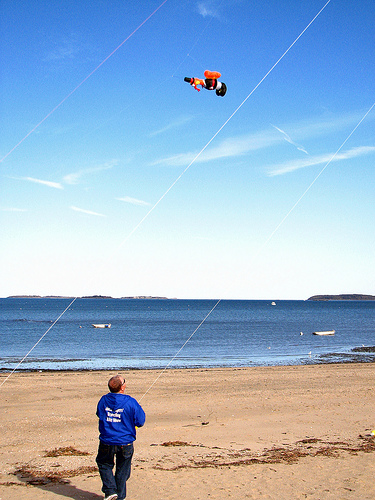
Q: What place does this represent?
A: It represents the beach.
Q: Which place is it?
A: It is a beach.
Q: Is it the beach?
A: Yes, it is the beach.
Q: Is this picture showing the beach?
A: Yes, it is showing the beach.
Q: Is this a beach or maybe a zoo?
A: It is a beach.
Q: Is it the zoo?
A: No, it is the beach.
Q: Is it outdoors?
A: Yes, it is outdoors.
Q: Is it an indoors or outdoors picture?
A: It is outdoors.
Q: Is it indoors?
A: No, it is outdoors.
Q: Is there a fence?
A: No, there are no fences.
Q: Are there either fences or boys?
A: No, there are no fences or boys.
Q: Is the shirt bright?
A: Yes, the shirt is bright.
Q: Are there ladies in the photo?
A: No, there are no ladies.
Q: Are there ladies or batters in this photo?
A: No, there are no ladies or batters.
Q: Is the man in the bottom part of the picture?
A: Yes, the man is in the bottom of the image.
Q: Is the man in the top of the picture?
A: No, the man is in the bottom of the image.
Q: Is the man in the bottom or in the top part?
A: The man is in the bottom of the image.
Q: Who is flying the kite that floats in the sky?
A: The man is flying the kite.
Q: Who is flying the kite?
A: The man is flying the kite.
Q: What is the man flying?
A: The man is flying the kite.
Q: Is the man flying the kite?
A: Yes, the man is flying the kite.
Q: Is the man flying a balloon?
A: No, the man is flying the kite.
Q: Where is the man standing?
A: The man is standing at the beach.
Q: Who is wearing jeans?
A: The man is wearing jeans.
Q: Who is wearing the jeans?
A: The man is wearing jeans.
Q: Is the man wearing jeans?
A: Yes, the man is wearing jeans.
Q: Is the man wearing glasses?
A: No, the man is wearing jeans.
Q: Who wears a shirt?
A: The man wears a shirt.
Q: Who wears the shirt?
A: The man wears a shirt.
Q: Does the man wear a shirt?
A: Yes, the man wears a shirt.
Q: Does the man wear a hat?
A: No, the man wears a shirt.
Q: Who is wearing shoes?
A: The man is wearing shoes.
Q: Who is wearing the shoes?
A: The man is wearing shoes.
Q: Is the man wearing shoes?
A: Yes, the man is wearing shoes.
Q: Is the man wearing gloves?
A: No, the man is wearing shoes.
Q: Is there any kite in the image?
A: Yes, there is a kite.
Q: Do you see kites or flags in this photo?
A: Yes, there is a kite.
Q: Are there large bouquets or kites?
A: Yes, there is a large kite.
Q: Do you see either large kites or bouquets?
A: Yes, there is a large kite.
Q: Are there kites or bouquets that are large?
A: Yes, the kite is large.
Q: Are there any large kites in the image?
A: Yes, there is a large kite.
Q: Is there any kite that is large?
A: Yes, there is a kite that is large.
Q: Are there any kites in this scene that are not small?
A: Yes, there is a large kite.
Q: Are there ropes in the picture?
A: No, there are no ropes.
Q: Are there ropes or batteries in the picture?
A: No, there are no ropes or batteries.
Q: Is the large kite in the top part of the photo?
A: Yes, the kite is in the top of the image.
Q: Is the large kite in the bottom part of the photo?
A: No, the kite is in the top of the image.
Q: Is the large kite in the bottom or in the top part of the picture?
A: The kite is in the top of the image.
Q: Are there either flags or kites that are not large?
A: No, there is a kite but it is large.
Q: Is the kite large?
A: Yes, the kite is large.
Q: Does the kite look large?
A: Yes, the kite is large.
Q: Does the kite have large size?
A: Yes, the kite is large.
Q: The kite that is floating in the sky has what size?
A: The kite is large.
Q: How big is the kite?
A: The kite is large.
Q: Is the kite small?
A: No, the kite is large.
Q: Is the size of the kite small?
A: No, the kite is large.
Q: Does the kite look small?
A: No, the kite is large.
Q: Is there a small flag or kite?
A: No, there is a kite but it is large.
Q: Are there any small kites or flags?
A: No, there is a kite but it is large.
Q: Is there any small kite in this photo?
A: No, there is a kite but it is large.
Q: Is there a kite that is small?
A: No, there is a kite but it is large.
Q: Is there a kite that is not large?
A: No, there is a kite but it is large.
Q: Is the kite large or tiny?
A: The kite is large.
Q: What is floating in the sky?
A: The kite is floating in the sky.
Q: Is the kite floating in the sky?
A: Yes, the kite is floating in the sky.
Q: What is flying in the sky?
A: The kite is flying in the sky.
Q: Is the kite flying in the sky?
A: Yes, the kite is flying in the sky.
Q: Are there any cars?
A: No, there are no cars.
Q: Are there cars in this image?
A: No, there are no cars.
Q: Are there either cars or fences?
A: No, there are no cars or fences.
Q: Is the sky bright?
A: Yes, the sky is bright.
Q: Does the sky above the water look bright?
A: Yes, the sky is bright.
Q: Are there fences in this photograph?
A: No, there are no fences.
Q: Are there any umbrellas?
A: No, there are no umbrellas.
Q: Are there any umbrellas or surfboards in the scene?
A: No, there are no umbrellas or surfboards.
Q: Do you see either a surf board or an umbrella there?
A: No, there are no umbrellas or surfboards.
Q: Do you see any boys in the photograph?
A: No, there are no boys.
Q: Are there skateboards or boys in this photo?
A: No, there are no boys or skateboards.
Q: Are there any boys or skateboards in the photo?
A: No, there are no boys or skateboards.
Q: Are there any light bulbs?
A: No, there are no light bulbs.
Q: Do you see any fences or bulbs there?
A: No, there are no bulbs or fences.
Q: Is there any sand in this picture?
A: Yes, there is sand.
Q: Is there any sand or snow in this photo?
A: Yes, there is sand.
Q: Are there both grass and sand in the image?
A: No, there is sand but no grass.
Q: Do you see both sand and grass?
A: No, there is sand but no grass.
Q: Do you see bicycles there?
A: No, there are no bicycles.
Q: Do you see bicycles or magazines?
A: No, there are no bicycles or magazines.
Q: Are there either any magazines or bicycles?
A: No, there are no bicycles or magazines.